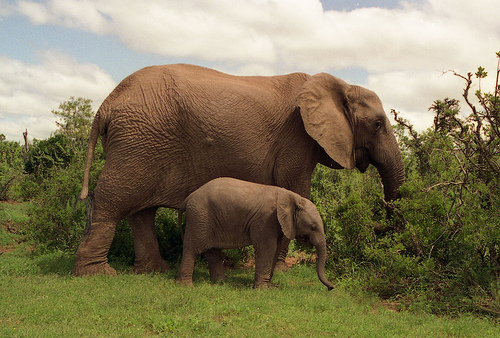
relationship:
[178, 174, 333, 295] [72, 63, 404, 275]
elephant os beside mother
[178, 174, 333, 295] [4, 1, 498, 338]
elephant in shot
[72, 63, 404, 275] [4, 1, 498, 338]
elephant in shot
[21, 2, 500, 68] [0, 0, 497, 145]
cloud in sky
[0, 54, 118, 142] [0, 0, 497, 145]
cloud in sky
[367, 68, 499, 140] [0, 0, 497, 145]
cloud in sky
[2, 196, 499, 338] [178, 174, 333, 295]
grass around elephant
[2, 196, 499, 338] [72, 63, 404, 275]
grass around elephant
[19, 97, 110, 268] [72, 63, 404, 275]
tree behind elephant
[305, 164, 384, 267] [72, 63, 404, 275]
tree behind elephant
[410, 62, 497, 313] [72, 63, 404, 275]
tree behind elephant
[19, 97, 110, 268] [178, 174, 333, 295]
tree behind elephant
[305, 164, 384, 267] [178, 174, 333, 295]
tree behind elephant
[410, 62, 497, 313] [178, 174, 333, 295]
tree behind elephant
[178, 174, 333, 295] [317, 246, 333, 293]
elephant has trunk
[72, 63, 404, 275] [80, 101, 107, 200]
elephant has tail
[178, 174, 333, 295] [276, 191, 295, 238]
elephant has ear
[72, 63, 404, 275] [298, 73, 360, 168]
elephant has ear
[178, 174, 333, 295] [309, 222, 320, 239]
elephant has eye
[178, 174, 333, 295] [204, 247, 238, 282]
elephant has leg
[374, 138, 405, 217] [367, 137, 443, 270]
trunk in bushes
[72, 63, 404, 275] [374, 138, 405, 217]
elephant has trunk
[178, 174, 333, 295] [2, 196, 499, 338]
elephant in grass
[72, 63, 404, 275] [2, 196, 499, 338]
elephant in grass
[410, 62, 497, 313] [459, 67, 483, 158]
tree has branches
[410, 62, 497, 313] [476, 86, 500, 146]
tree has branches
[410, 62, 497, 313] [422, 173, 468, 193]
tree has branches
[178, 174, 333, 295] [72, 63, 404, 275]
elephant with mother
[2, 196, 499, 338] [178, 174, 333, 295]
grass under elephant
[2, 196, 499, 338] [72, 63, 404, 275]
grass under elephant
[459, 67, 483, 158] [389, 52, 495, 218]
branches are in air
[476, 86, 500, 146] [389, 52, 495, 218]
branches are in air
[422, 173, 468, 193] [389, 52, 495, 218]
branches are in air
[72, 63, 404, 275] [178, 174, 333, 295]
mother with elephant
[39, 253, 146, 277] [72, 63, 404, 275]
shadow from elephant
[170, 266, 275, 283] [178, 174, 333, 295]
shadow from elephant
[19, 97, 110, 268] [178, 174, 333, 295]
tree next to elephant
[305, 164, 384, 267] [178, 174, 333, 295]
tree next to elephant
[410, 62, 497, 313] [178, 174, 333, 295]
tree next to elephant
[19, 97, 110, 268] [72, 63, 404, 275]
tree next to elephant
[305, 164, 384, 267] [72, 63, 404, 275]
tree next to elephant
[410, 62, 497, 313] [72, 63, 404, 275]
tree next to elephant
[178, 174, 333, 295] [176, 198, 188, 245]
elephant has tail